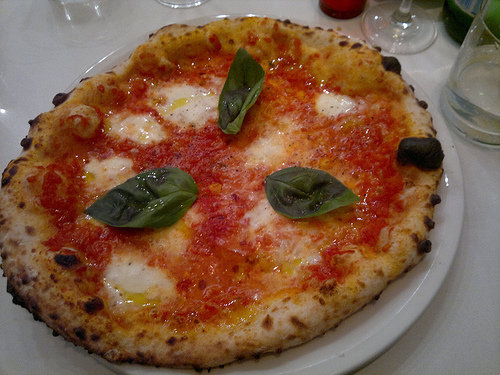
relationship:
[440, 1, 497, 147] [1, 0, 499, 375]
glass on table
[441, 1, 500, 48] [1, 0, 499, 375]
bottle on table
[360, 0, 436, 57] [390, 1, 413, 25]
wine glass has stem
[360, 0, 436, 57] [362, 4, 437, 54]
wine glass has base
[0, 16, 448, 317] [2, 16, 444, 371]
cheese on pizza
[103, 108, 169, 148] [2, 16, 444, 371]
cheese on pizza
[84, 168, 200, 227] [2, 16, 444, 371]
spinach on pizza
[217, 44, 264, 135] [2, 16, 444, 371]
spinach on pizza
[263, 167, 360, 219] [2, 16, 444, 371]
spinach on pizza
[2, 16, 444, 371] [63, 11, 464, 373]
pizza on plate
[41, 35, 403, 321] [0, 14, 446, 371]
sauce on crust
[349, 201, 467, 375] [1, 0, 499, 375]
shadow on table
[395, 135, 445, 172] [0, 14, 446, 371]
spot on crust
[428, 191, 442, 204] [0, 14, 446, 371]
spot on crust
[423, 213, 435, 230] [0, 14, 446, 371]
spot on crust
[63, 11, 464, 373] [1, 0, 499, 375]
plate on table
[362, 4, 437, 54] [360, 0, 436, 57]
base of wine glass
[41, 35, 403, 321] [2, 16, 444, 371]
sauce on pizza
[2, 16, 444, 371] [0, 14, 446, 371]
pizza has crust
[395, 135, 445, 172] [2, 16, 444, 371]
spot on pizza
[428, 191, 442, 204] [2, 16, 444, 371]
spot on pizza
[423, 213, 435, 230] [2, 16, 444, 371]
spot on pizza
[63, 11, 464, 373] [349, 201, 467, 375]
plate has shadow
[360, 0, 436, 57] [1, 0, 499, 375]
wine glass on table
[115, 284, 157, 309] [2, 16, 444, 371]
grease on pizza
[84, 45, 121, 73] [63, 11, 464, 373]
glare on plate